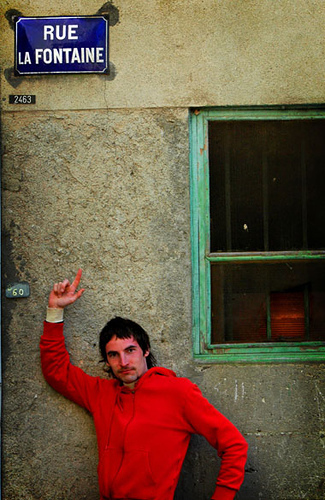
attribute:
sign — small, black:
[9, 91, 38, 106]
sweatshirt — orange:
[38, 317, 246, 497]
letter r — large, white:
[41, 24, 55, 42]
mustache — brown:
[114, 362, 138, 376]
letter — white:
[41, 23, 55, 41]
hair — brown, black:
[97, 314, 153, 375]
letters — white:
[13, 18, 102, 67]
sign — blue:
[16, 17, 110, 77]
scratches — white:
[225, 374, 248, 404]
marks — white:
[229, 377, 246, 404]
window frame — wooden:
[186, 105, 323, 358]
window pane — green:
[191, 257, 214, 356]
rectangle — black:
[6, 93, 39, 106]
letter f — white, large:
[34, 48, 45, 63]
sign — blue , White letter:
[8, 13, 117, 78]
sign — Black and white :
[9, 7, 119, 79]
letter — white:
[55, 24, 66, 41]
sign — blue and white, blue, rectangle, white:
[12, 12, 111, 76]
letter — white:
[17, 52, 24, 65]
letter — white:
[24, 51, 32, 65]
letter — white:
[41, 48, 51, 63]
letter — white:
[52, 46, 62, 64]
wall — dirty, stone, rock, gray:
[1, 1, 314, 497]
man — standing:
[38, 267, 248, 499]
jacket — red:
[37, 320, 248, 499]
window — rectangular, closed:
[189, 106, 315, 363]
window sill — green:
[193, 340, 315, 361]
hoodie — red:
[38, 319, 247, 498]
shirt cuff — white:
[44, 306, 64, 324]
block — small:
[4, 282, 30, 299]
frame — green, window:
[189, 105, 315, 364]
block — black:
[7, 93, 35, 104]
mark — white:
[237, 216, 254, 233]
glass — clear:
[212, 117, 316, 250]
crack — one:
[249, 421, 324, 442]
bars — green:
[219, 134, 304, 334]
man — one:
[100, 317, 176, 449]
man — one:
[102, 321, 159, 405]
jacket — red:
[38, 371, 243, 490]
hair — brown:
[103, 319, 133, 339]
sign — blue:
[10, 11, 119, 83]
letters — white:
[32, 21, 79, 42]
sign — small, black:
[4, 88, 35, 107]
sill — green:
[193, 340, 324, 364]